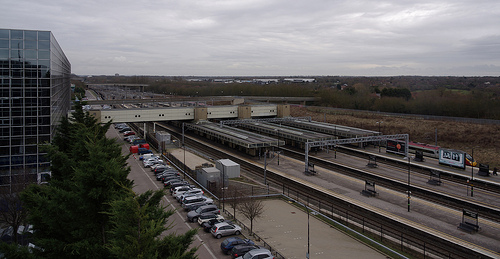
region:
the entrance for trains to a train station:
[125, 86, 499, 246]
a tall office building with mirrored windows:
[3, 22, 76, 232]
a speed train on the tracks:
[395, 129, 481, 166]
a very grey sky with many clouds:
[216, 13, 485, 75]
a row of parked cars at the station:
[127, 141, 264, 256]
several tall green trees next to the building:
[38, 114, 179, 252]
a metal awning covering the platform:
[198, 119, 288, 163]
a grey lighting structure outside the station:
[300, 128, 412, 166]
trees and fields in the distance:
[342, 76, 487, 110]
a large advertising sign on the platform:
[438, 147, 465, 170]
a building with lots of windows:
[2, 24, 80, 217]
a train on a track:
[392, 127, 484, 172]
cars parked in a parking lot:
[151, 147, 225, 254]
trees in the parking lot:
[230, 184, 267, 236]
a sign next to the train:
[439, 141, 471, 176]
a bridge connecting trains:
[82, 99, 254, 116]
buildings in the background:
[188, 71, 336, 92]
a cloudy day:
[85, 18, 379, 73]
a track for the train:
[103, 86, 134, 115]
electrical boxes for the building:
[208, 141, 245, 206]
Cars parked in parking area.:
[166, 171, 261, 257]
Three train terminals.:
[192, 121, 376, 153]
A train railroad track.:
[189, 134, 234, 157]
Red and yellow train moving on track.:
[413, 136, 480, 171]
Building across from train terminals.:
[3, 24, 75, 214]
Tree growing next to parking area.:
[3, 114, 198, 257]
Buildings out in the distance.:
[185, 69, 345, 97]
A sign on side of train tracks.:
[436, 145, 466, 172]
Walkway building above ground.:
[93, 103, 278, 125]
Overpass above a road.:
[278, 91, 331, 107]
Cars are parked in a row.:
[122, 142, 238, 254]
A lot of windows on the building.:
[21, 52, 55, 162]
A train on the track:
[397, 133, 479, 166]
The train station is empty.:
[281, 155, 461, 217]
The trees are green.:
[63, 128, 137, 257]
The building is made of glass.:
[13, 31, 63, 158]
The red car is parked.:
[128, 142, 160, 157]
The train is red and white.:
[392, 144, 478, 168]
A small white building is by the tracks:
[217, 153, 246, 188]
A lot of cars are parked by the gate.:
[162, 153, 254, 253]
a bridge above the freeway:
[92, 100, 294, 127]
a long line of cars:
[138, 147, 273, 257]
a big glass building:
[3, 28, 72, 187]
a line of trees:
[323, 86, 480, 120]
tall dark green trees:
[26, 122, 180, 257]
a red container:
[129, 141, 149, 155]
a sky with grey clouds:
[270, 15, 497, 62]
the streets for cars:
[275, 146, 488, 242]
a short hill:
[325, 73, 496, 89]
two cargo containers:
[196, 157, 238, 189]